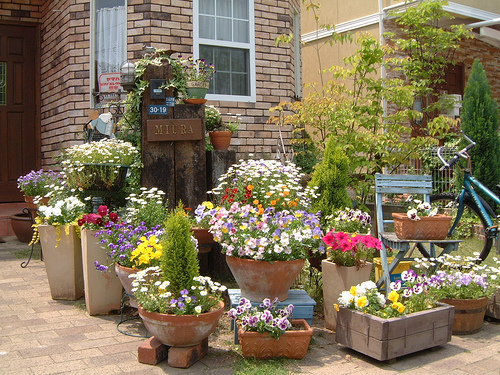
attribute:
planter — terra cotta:
[134, 305, 206, 349]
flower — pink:
[372, 237, 383, 253]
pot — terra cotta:
[132, 290, 231, 347]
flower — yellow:
[388, 302, 405, 316]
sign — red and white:
[97, 70, 126, 95]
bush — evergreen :
[157, 201, 201, 302]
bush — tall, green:
[323, 38, 495, 220]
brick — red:
[126, 339, 178, 372]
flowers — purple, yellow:
[96, 219, 163, 268]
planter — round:
[111, 262, 160, 308]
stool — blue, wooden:
[222, 284, 317, 344]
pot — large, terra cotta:
[222, 250, 306, 300]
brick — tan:
[15, 309, 60, 321]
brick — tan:
[69, 335, 120, 351]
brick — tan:
[29, 355, 91, 373]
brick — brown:
[53, 321, 103, 335]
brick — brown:
[16, 340, 74, 359]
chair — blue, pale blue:
[368, 165, 462, 289]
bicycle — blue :
[413, 130, 499, 274]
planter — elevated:
[122, 199, 238, 342]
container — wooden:
[327, 305, 465, 363]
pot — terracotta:
[220, 250, 319, 309]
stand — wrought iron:
[7, 194, 43, 242]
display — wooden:
[139, 60, 209, 213]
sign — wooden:
[142, 115, 203, 142]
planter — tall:
[99, 59, 233, 319]